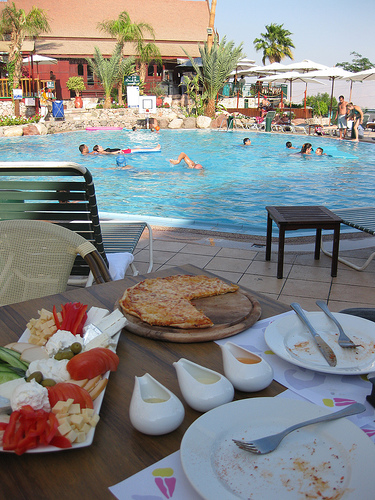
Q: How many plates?
A: 3.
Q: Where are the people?
A: Swimming.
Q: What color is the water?
A: Blue.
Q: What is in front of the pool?
A: Chairs.